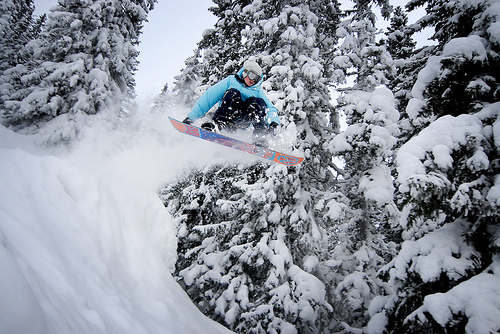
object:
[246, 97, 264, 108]
knee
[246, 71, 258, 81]
sunglasses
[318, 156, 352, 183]
tree branch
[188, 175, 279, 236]
branches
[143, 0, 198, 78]
sky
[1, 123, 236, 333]
hill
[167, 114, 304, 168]
snowboard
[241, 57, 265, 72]
hat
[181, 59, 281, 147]
snowboarder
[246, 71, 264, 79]
goggles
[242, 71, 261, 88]
face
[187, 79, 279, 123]
jacket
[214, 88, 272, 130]
pants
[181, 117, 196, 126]
hand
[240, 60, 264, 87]
head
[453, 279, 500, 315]
snow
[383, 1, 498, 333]
tree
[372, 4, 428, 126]
tree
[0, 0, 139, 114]
tree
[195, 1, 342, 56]
trees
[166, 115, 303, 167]
designs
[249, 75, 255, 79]
eyes